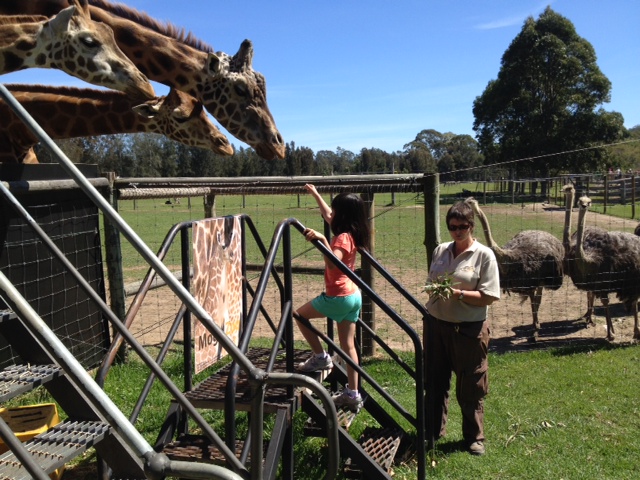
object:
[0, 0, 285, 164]
giraffes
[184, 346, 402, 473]
stairs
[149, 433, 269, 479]
stairs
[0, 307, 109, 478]
stairs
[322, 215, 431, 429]
rails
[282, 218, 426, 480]
rails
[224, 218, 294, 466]
rails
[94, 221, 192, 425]
rails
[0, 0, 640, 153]
sky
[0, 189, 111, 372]
fencing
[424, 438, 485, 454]
shoes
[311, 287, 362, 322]
shorts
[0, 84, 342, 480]
metal stairs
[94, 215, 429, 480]
rails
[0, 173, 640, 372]
railings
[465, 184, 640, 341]
ostrich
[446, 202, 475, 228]
hair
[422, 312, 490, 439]
pants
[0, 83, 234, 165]
giraffe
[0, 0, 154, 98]
giraffe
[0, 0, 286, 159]
giraffe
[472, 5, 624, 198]
tree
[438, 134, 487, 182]
tree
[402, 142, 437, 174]
tree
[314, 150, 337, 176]
tree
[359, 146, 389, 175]
tree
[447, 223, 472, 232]
sunglasses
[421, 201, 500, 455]
woman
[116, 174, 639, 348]
fence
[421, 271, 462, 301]
food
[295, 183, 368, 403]
girl